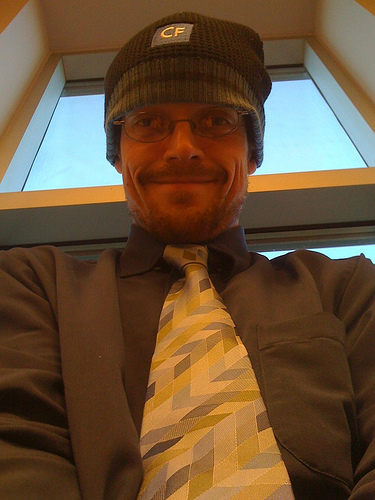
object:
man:
[0, 13, 375, 500]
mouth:
[146, 171, 219, 188]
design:
[137, 243, 295, 500]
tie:
[138, 245, 295, 500]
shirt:
[0, 223, 375, 500]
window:
[17, 64, 374, 261]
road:
[137, 244, 222, 425]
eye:
[135, 117, 163, 128]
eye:
[201, 114, 232, 128]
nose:
[162, 113, 204, 165]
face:
[119, 101, 249, 244]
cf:
[161, 27, 185, 38]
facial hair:
[122, 160, 255, 248]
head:
[103, 11, 272, 244]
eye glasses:
[113, 110, 250, 143]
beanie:
[104, 11, 273, 168]